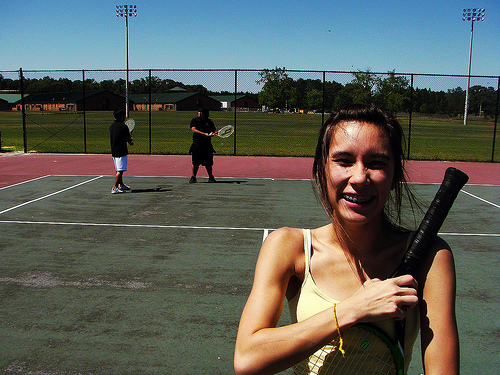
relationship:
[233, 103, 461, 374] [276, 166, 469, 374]
girl holding racket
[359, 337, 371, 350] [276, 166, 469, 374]
letter p on racket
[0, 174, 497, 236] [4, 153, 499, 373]
white lines on ground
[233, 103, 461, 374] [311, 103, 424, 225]
girl has black hair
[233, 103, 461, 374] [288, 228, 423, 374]
girl wearing tan shirt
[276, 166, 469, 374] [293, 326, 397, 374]
racket has inside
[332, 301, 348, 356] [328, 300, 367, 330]
yellow bracelet on wrist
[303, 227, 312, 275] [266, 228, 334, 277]
strap on shoulder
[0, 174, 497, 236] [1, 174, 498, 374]
white lines on court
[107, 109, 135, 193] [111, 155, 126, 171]
man wearing white shorts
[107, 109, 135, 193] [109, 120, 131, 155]
person wearing black shirt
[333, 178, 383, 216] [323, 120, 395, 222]
smile on face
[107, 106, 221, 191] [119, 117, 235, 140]
people holding rackets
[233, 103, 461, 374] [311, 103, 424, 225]
girl with hair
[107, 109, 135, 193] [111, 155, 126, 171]
person wearing white shorts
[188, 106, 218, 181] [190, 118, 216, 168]
person wearing black clothing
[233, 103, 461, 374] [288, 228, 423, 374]
girl with sleeveless shirt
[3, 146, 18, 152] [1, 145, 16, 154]
dough on plate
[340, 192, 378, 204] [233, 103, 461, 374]
teeth of girl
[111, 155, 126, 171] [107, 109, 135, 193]
white shorts of person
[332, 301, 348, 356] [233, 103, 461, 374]
yellow bracelet on girl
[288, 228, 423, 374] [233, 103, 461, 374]
tan shirt of girl